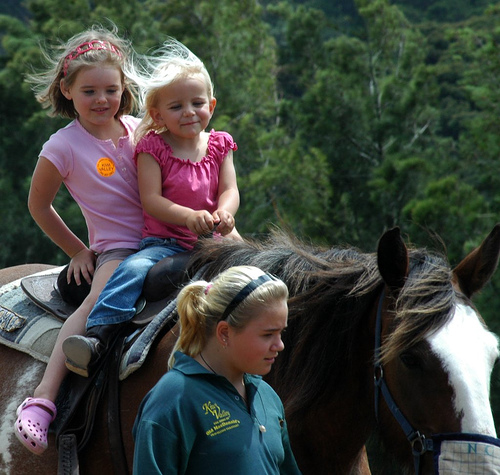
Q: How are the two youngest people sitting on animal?
A: In saddle.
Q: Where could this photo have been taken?
A: Farm.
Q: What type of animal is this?
A: Horse.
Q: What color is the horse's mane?
A: Brown.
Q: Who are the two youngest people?
A: Young girls.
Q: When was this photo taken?
A: Daytime.